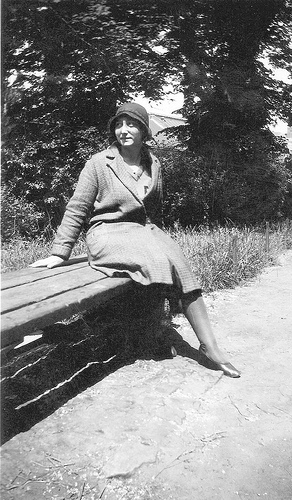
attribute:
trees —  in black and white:
[164, 24, 262, 144]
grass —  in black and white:
[200, 236, 229, 266]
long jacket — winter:
[51, 143, 202, 291]